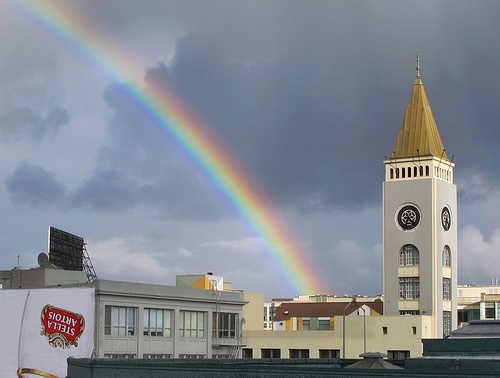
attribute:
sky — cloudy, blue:
[2, 2, 495, 286]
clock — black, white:
[391, 197, 421, 233]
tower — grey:
[376, 50, 463, 344]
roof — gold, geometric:
[385, 50, 451, 164]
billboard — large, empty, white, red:
[34, 302, 87, 350]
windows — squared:
[101, 302, 140, 341]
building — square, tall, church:
[10, 279, 247, 369]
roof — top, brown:
[13, 266, 248, 304]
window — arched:
[399, 239, 419, 269]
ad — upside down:
[4, 288, 90, 376]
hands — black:
[403, 215, 413, 226]